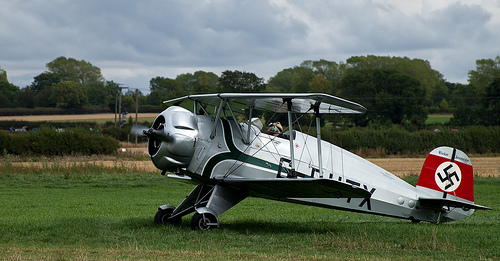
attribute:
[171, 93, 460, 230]
plane — bilane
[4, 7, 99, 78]
clouds — storm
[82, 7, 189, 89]
clouds — storm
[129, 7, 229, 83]
clouds — storm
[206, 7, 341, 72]
clouds — storm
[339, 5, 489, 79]
clouds — storm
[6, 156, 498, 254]
field — grass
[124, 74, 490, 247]
nazi plane — historical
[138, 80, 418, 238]
plane — small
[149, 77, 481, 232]
airplane — small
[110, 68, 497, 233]
plane — war plane, Nazi war plane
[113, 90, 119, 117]
poles — electrical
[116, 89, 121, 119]
poles — electrical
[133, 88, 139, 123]
poles — electrical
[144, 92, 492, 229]
airplane — historical, small, white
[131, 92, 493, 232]
plane — german, old german, silver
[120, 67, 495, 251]
plane — german